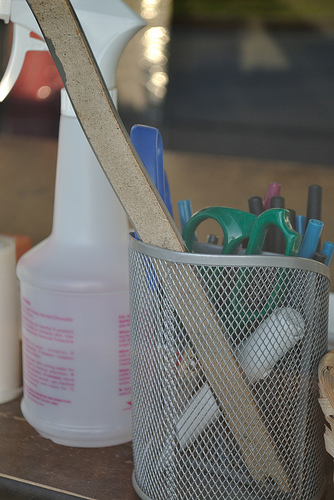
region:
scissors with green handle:
[180, 204, 300, 407]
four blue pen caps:
[177, 199, 332, 262]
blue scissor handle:
[130, 122, 173, 289]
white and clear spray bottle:
[0, 0, 135, 447]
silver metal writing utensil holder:
[128, 231, 332, 499]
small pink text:
[19, 296, 131, 411]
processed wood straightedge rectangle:
[25, 0, 288, 491]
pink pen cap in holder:
[266, 180, 280, 209]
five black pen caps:
[206, 184, 328, 262]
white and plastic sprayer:
[0, 0, 147, 114]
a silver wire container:
[119, 193, 306, 496]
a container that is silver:
[108, 226, 301, 462]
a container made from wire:
[114, 227, 326, 452]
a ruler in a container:
[117, 222, 332, 440]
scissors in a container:
[101, 198, 320, 460]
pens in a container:
[118, 213, 331, 473]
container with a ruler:
[121, 213, 315, 461]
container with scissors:
[137, 222, 331, 478]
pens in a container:
[151, 201, 270, 445]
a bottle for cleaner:
[16, 224, 211, 466]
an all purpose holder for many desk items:
[118, 210, 332, 497]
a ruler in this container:
[26, 0, 295, 494]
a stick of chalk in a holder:
[150, 295, 309, 474]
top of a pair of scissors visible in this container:
[179, 200, 305, 255]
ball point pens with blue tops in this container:
[292, 211, 325, 258]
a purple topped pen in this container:
[259, 175, 285, 209]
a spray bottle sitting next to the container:
[1, 0, 155, 451]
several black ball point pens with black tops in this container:
[243, 181, 325, 250]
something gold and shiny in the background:
[116, 0, 177, 133]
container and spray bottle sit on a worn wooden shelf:
[1, 385, 172, 499]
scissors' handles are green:
[175, 195, 290, 349]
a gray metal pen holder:
[102, 240, 333, 493]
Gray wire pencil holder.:
[128, 232, 331, 499]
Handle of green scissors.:
[183, 204, 301, 254]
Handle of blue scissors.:
[128, 123, 174, 217]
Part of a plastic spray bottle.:
[15, 89, 132, 447]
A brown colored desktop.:
[0, 389, 141, 498]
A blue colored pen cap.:
[298, 217, 324, 255]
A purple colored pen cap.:
[264, 180, 284, 210]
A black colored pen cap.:
[306, 181, 323, 228]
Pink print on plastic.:
[20, 294, 75, 408]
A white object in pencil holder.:
[230, 305, 304, 387]